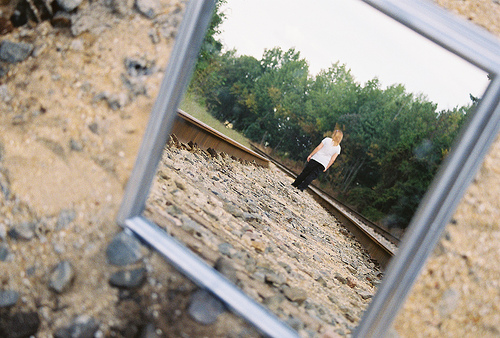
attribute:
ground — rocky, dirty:
[0, 78, 82, 223]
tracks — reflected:
[165, 104, 402, 260]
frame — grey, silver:
[79, 7, 237, 253]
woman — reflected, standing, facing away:
[291, 125, 353, 196]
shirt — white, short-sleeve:
[321, 130, 349, 165]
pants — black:
[298, 147, 323, 196]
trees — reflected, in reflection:
[208, 52, 475, 217]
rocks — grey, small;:
[229, 131, 366, 318]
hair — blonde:
[331, 132, 346, 149]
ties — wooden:
[183, 118, 355, 300]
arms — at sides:
[302, 136, 344, 168]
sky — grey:
[221, 4, 484, 96]